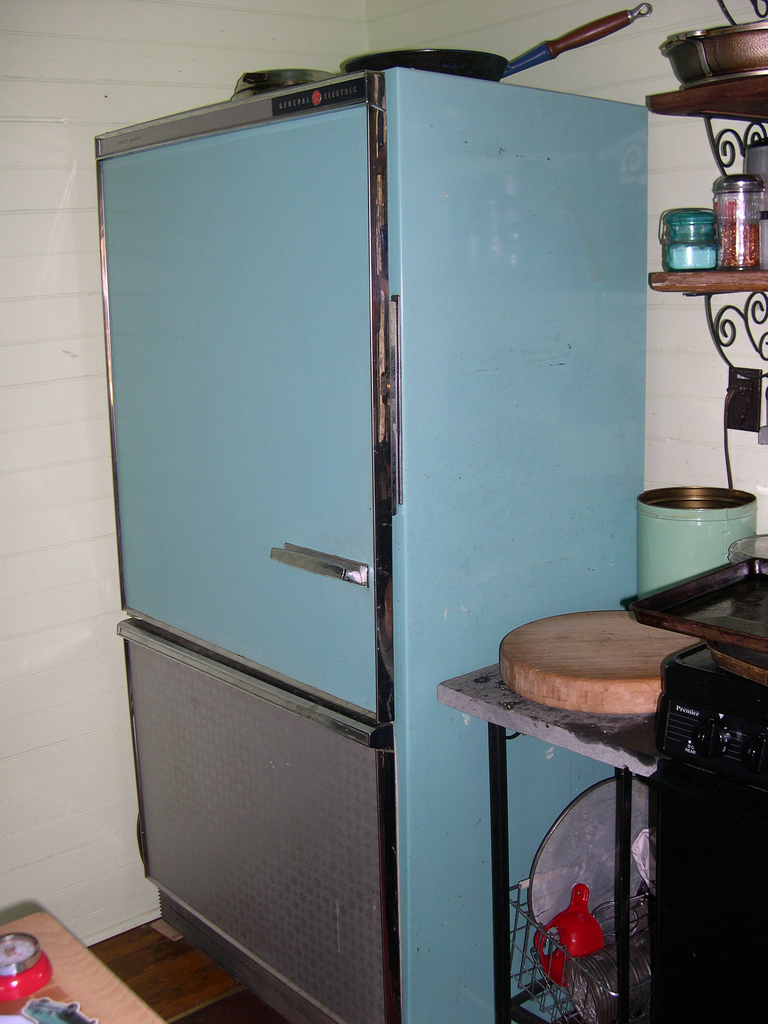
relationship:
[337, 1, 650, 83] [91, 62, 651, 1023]
skillet on fridge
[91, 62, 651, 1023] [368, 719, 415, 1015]
fridge has line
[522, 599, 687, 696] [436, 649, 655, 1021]
tray on table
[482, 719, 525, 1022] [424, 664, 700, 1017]
leg of table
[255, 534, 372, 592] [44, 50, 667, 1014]
handle on fridge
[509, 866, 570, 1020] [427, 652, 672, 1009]
basket on table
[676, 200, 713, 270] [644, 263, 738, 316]
bottle on shelf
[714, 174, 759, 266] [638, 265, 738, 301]
bottle on shelf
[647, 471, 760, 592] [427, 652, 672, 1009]
jar on table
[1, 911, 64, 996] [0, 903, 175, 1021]
clock on table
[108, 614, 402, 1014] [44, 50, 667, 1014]
drawer on fridge